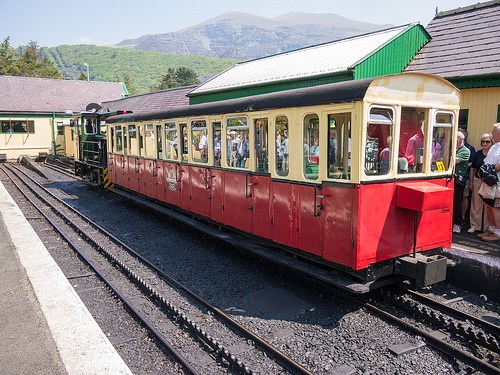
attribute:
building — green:
[362, 44, 404, 61]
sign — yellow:
[430, 159, 447, 174]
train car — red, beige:
[103, 69, 460, 295]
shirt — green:
[455, 143, 472, 187]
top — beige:
[108, 72, 460, 182]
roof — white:
[189, 24, 406, 94]